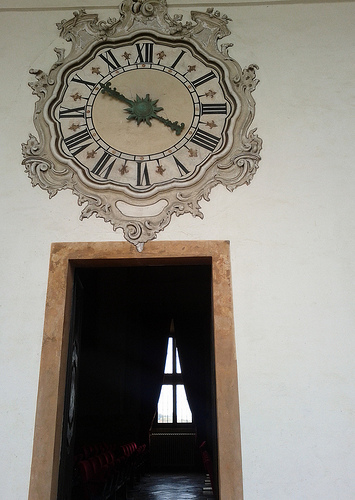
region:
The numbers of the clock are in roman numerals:
[11, 2, 276, 228]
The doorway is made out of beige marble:
[36, 239, 254, 495]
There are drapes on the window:
[137, 315, 200, 438]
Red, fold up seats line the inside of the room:
[81, 420, 174, 497]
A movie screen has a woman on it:
[66, 304, 108, 459]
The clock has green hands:
[94, 66, 197, 162]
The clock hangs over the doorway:
[39, 51, 273, 397]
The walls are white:
[251, 327, 344, 488]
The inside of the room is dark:
[75, 264, 207, 482]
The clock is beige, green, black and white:
[28, 9, 269, 227]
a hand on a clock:
[102, 78, 130, 107]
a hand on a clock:
[154, 112, 184, 138]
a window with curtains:
[146, 321, 203, 428]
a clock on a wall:
[36, 17, 255, 218]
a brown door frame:
[197, 241, 246, 370]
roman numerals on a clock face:
[69, 127, 123, 179]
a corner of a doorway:
[38, 236, 88, 270]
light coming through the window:
[151, 341, 208, 425]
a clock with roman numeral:
[72, 56, 214, 168]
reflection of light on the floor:
[151, 468, 193, 497]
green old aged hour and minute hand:
[88, 77, 198, 144]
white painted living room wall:
[249, 261, 347, 417]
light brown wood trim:
[213, 232, 245, 497]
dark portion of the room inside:
[91, 284, 186, 483]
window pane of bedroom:
[161, 332, 207, 475]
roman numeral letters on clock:
[132, 41, 156, 71]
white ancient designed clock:
[21, 2, 267, 263]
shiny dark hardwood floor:
[143, 461, 197, 498]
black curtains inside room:
[141, 319, 162, 410]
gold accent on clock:
[161, 52, 168, 64]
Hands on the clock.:
[93, 57, 198, 146]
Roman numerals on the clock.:
[109, 131, 222, 214]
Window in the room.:
[115, 317, 200, 498]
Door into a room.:
[9, 202, 352, 395]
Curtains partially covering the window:
[129, 309, 234, 464]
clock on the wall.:
[12, 20, 326, 244]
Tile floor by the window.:
[138, 443, 204, 495]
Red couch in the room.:
[80, 420, 157, 488]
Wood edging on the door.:
[217, 251, 292, 438]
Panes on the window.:
[150, 350, 221, 455]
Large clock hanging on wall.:
[24, 3, 243, 211]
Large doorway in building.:
[39, 240, 259, 497]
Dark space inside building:
[70, 266, 210, 470]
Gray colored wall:
[246, 332, 323, 428]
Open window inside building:
[146, 328, 208, 445]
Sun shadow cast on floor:
[139, 451, 226, 498]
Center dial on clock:
[87, 60, 212, 164]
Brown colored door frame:
[26, 175, 319, 357]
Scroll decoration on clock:
[10, 122, 148, 231]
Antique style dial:
[100, 62, 189, 151]